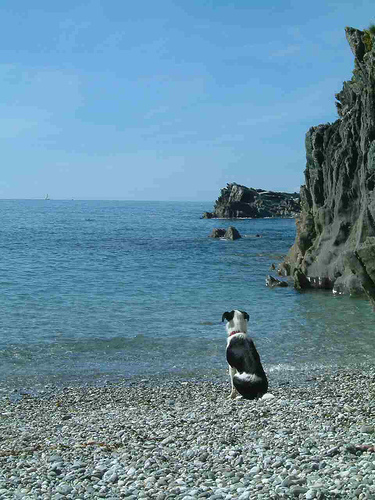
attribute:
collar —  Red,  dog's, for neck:
[229, 331, 244, 334]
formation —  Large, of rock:
[198, 180, 298, 220]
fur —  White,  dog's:
[227, 332, 249, 339]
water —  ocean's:
[0, 201, 199, 375]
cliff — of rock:
[275, 27, 373, 298]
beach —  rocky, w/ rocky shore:
[0, 397, 373, 497]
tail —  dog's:
[260, 392, 277, 398]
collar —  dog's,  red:
[227, 330, 244, 335]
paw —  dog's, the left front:
[223, 389, 235, 399]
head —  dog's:
[220, 310, 252, 328]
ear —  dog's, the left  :
[221, 312, 231, 322]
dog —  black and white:
[220, 308, 269, 400]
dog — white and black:
[223, 310, 279, 402]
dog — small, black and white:
[219, 308, 279, 405]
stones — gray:
[0, 363, 375, 498]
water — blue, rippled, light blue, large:
[0, 197, 375, 394]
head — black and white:
[219, 308, 251, 333]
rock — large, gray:
[264, 22, 373, 300]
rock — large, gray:
[198, 180, 306, 218]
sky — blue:
[0, 0, 375, 203]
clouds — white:
[1, 2, 373, 204]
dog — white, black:
[219, 308, 273, 399]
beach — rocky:
[0, 367, 374, 498]